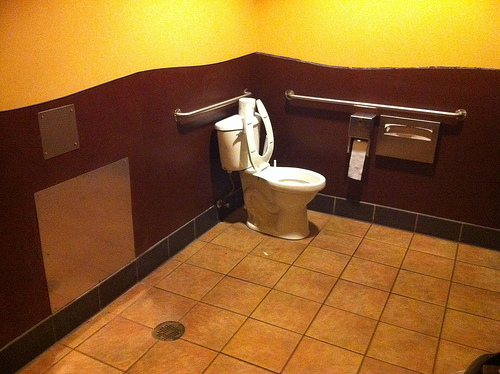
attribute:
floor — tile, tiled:
[155, 254, 330, 351]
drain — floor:
[133, 309, 194, 362]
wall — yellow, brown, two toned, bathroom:
[60, 19, 135, 88]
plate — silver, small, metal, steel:
[30, 91, 94, 167]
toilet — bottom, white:
[241, 126, 341, 214]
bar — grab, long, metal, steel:
[174, 84, 265, 139]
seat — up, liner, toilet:
[224, 94, 302, 174]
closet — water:
[243, 152, 323, 213]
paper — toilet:
[344, 136, 379, 192]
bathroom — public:
[53, 10, 482, 313]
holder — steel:
[141, 72, 264, 152]